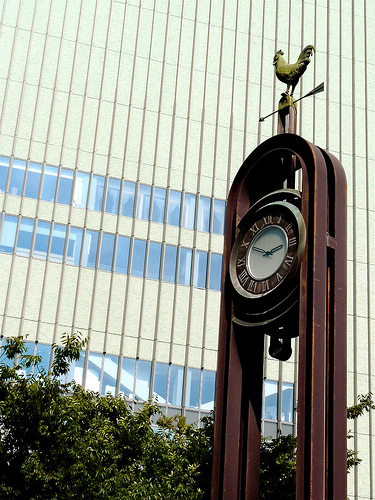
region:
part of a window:
[234, 389, 246, 399]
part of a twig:
[162, 439, 167, 449]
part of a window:
[180, 379, 184, 384]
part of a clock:
[252, 402, 256, 430]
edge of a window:
[164, 378, 170, 388]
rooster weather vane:
[259, 49, 322, 132]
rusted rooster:
[254, 48, 324, 98]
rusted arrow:
[254, 84, 332, 122]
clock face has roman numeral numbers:
[224, 196, 316, 325]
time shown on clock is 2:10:
[233, 219, 302, 307]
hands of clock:
[251, 238, 286, 258]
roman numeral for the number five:
[272, 271, 287, 288]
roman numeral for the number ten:
[241, 237, 251, 249]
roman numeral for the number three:
[283, 233, 302, 247]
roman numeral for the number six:
[259, 274, 270, 291]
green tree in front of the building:
[0, 332, 374, 499]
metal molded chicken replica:
[272, 43, 314, 91]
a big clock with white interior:
[226, 186, 303, 332]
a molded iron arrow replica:
[259, 81, 325, 122]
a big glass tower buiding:
[0, 1, 370, 499]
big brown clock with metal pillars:
[211, 44, 346, 498]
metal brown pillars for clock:
[211, 323, 347, 499]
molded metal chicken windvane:
[257, 44, 325, 123]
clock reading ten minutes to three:
[235, 214, 299, 294]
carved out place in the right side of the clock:
[316, 143, 351, 498]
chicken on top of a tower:
[260, 38, 321, 96]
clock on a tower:
[229, 201, 303, 294]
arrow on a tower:
[260, 78, 331, 121]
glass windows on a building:
[53, 166, 217, 284]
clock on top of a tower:
[225, 203, 304, 309]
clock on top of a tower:
[210, 204, 315, 296]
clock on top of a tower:
[216, 208, 311, 296]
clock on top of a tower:
[225, 202, 319, 301]